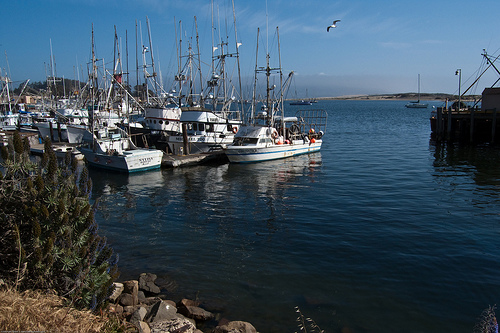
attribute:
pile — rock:
[93, 268, 260, 330]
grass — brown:
[0, 262, 120, 331]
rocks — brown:
[102, 268, 255, 331]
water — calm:
[229, 182, 390, 281]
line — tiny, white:
[164, 299, 172, 311]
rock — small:
[148, 297, 180, 324]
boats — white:
[58, 99, 356, 187]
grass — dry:
[15, 286, 102, 331]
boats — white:
[215, 108, 339, 180]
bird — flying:
[325, 17, 340, 32]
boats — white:
[37, 23, 306, 192]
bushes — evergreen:
[5, 177, 130, 292]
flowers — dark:
[58, 188, 73, 209]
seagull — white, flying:
[320, 17, 344, 35]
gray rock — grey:
[176, 297, 223, 322]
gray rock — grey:
[137, 271, 180, 293]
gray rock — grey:
[213, 320, 259, 332]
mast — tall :
[248, 0, 294, 138]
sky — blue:
[4, 11, 494, 93]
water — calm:
[315, 190, 497, 285]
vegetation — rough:
[4, 137, 118, 304]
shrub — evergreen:
[3, 154, 95, 295]